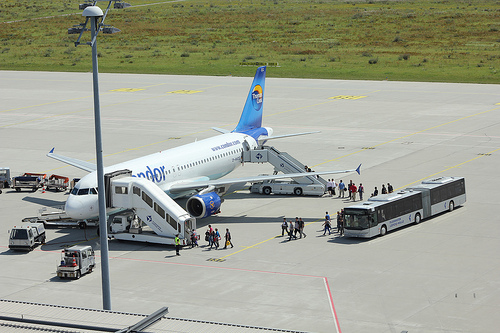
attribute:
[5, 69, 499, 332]
runway — big, white, grey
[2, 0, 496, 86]
grass — green, short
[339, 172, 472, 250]
bus — huge, big, parked, long, black, white